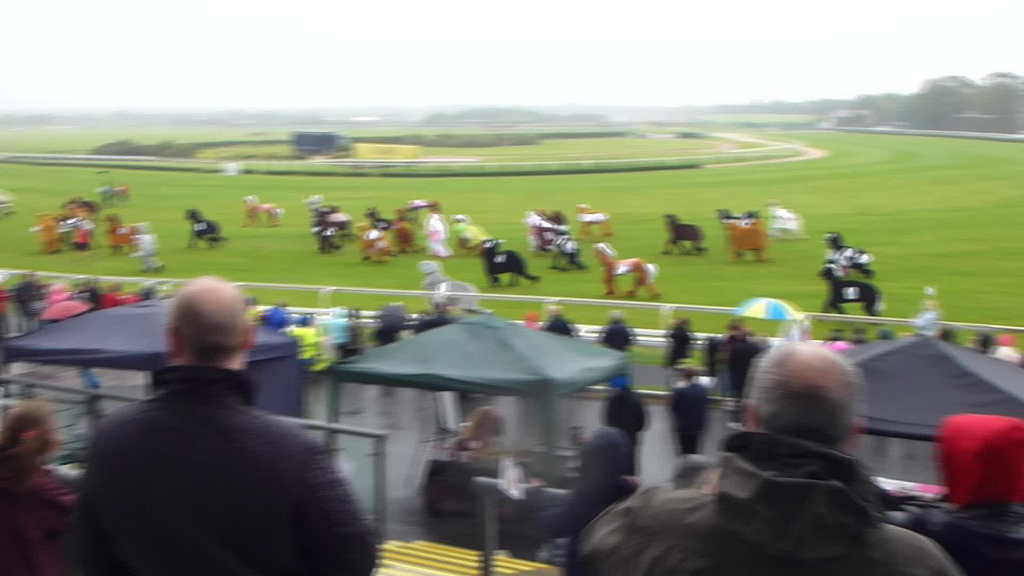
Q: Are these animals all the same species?
A: Yes, all the animals are horses.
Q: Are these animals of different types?
A: No, all the animals are horses.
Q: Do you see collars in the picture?
A: Yes, there is a collar.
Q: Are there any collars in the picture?
A: Yes, there is a collar.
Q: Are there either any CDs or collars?
A: Yes, there is a collar.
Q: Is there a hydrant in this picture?
A: No, there are no fire hydrants.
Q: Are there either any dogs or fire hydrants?
A: No, there are no fire hydrants or dogs.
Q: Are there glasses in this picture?
A: No, there are no glasses.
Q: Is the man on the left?
A: Yes, the man is on the left of the image.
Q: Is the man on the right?
A: No, the man is on the left of the image.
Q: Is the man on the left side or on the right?
A: The man is on the left of the image.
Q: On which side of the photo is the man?
A: The man is on the left of the image.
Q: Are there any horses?
A: Yes, there is a horse.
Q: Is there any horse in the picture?
A: Yes, there is a horse.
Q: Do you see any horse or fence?
A: Yes, there is a horse.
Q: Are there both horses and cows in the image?
A: No, there is a horse but no cows.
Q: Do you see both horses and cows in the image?
A: No, there is a horse but no cows.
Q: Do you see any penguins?
A: No, there are no penguins.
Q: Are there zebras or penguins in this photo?
A: No, there are no penguins or zebras.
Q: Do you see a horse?
A: Yes, there is a horse.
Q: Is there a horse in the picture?
A: Yes, there is a horse.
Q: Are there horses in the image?
A: Yes, there is a horse.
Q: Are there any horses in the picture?
A: Yes, there is a horse.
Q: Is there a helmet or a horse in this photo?
A: Yes, there is a horse.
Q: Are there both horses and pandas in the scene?
A: No, there is a horse but no pandas.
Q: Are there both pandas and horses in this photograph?
A: No, there is a horse but no pandas.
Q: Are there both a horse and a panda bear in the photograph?
A: No, there is a horse but no pandas.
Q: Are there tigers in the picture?
A: No, there are no tigers.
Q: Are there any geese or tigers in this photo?
A: No, there are no tigers or geese.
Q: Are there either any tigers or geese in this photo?
A: No, there are no tigers or geese.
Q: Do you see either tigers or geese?
A: No, there are no tigers or geese.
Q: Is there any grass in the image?
A: Yes, there is grass.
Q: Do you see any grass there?
A: Yes, there is grass.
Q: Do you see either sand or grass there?
A: Yes, there is grass.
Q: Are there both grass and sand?
A: No, there is grass but no sand.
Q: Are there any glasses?
A: No, there are no glasses.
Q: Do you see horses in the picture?
A: Yes, there are horses.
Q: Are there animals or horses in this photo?
A: Yes, there are horses.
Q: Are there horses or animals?
A: Yes, there are horses.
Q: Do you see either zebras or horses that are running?
A: Yes, the horses are running.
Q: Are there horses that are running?
A: Yes, there are horses that are running.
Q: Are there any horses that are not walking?
A: Yes, there are horses that are running.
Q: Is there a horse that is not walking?
A: Yes, there are horses that are running.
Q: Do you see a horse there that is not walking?
A: Yes, there are horses that are running .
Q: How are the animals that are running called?
A: The animals are horses.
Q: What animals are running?
A: The animals are horses.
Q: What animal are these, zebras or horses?
A: These are horses.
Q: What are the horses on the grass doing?
A: The horses are running.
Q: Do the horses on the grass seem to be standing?
A: No, the horses are running.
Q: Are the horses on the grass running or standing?
A: The horses are running.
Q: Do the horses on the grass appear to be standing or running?
A: The horses are running.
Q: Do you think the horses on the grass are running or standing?
A: The horses are running.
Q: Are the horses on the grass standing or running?
A: The horses are running.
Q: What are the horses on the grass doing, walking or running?
A: The horses are running.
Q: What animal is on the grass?
A: The horses are on the grass.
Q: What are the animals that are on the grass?
A: The animals are horses.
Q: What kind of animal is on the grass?
A: The animals are horses.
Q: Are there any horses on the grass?
A: Yes, there are horses on the grass.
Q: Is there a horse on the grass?
A: Yes, there are horses on the grass.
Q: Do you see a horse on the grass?
A: Yes, there are horses on the grass.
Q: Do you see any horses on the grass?
A: Yes, there are horses on the grass.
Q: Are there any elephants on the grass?
A: No, there are horses on the grass.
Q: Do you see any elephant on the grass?
A: No, there are horses on the grass.